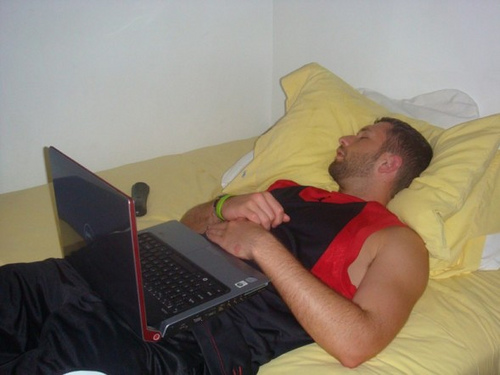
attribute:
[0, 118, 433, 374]
man — sleeping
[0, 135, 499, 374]
bed — twin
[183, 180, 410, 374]
shirt — red, black, sleeveless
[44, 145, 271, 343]
laptop — open, computer, red, grey, dell, black, reflective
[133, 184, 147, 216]
control — remote, black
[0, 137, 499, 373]
sheet — yellow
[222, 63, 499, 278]
pillowcase — yellow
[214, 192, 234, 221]
bracelet — yellow, here, green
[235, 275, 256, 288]
sticker — small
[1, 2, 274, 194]
wall — white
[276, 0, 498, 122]
wall — white